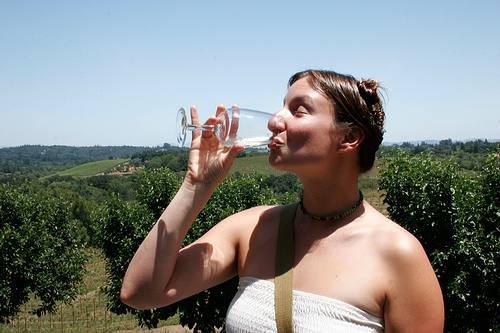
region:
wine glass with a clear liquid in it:
[177, 106, 279, 146]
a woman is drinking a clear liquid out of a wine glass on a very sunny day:
[120, 66, 442, 327]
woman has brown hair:
[265, 66, 385, 201]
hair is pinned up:
[285, 66, 381, 171]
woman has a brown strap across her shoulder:
[240, 190, 401, 330]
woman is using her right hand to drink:
[120, 70, 440, 330]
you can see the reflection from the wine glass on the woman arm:
[197, 240, 227, 280]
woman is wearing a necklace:
[292, 185, 362, 220]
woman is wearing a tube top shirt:
[225, 267, 380, 327]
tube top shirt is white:
[222, 275, 387, 328]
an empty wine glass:
[173, 107, 285, 152]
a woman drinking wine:
[133, 72, 440, 330]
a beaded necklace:
[290, 192, 372, 222]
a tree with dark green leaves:
[383, 144, 499, 308]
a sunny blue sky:
[4, 6, 491, 91]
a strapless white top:
[228, 277, 370, 332]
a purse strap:
[266, 207, 297, 331]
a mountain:
[6, 139, 119, 181]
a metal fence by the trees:
[16, 305, 101, 330]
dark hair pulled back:
[287, 67, 392, 165]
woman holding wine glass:
[88, 47, 460, 330]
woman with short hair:
[90, 61, 497, 201]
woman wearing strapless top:
[121, 52, 466, 330]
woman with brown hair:
[104, 33, 442, 328]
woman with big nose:
[127, 59, 446, 331]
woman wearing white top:
[141, 60, 471, 322]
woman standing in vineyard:
[104, 53, 449, 330]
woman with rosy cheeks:
[132, 53, 460, 317]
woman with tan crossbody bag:
[110, 57, 485, 332]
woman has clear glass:
[140, 39, 434, 330]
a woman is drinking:
[120, 72, 452, 332]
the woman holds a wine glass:
[171, 100, 281, 175]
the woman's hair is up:
[279, 66, 386, 178]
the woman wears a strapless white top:
[218, 275, 385, 330]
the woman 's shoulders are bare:
[230, 200, 427, 312]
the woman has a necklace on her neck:
[292, 192, 367, 220]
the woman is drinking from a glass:
[172, 65, 382, 177]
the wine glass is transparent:
[177, 105, 289, 153]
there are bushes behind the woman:
[5, 160, 497, 331]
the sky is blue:
[0, 2, 498, 148]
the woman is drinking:
[186, 88, 343, 184]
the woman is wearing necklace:
[284, 181, 399, 231]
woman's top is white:
[222, 263, 343, 331]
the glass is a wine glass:
[182, 103, 291, 150]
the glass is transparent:
[149, 88, 284, 173]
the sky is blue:
[35, 14, 160, 91]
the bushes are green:
[12, 165, 92, 260]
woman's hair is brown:
[295, 58, 392, 140]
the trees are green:
[20, 200, 79, 295]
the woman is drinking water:
[158, 90, 298, 182]